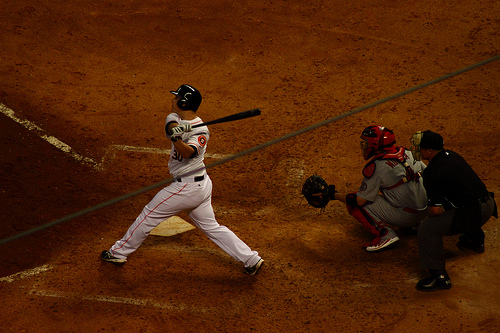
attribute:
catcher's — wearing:
[305, 125, 417, 251]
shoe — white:
[368, 229, 406, 255]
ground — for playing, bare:
[9, 6, 497, 326]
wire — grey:
[6, 55, 496, 234]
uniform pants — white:
[116, 178, 258, 267]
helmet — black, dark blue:
[165, 86, 203, 112]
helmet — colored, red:
[362, 122, 405, 160]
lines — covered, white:
[3, 99, 318, 317]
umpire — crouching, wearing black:
[411, 129, 496, 312]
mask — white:
[411, 132, 426, 154]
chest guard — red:
[363, 152, 405, 179]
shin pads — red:
[345, 199, 383, 238]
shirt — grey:
[363, 162, 428, 209]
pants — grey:
[368, 199, 426, 233]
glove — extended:
[298, 178, 348, 205]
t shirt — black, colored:
[426, 152, 485, 210]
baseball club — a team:
[98, 66, 490, 305]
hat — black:
[409, 129, 443, 151]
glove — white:
[172, 125, 198, 136]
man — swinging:
[104, 83, 264, 272]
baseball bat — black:
[166, 105, 264, 139]